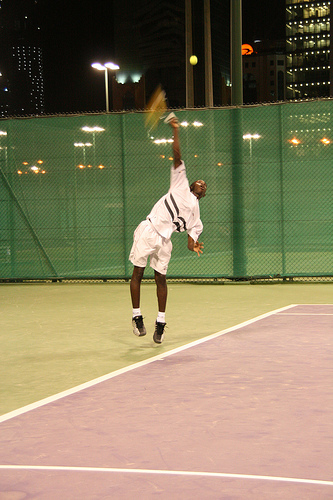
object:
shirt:
[145, 158, 204, 244]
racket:
[139, 88, 175, 137]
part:
[131, 410, 194, 435]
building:
[0, 0, 43, 118]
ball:
[188, 54, 197, 66]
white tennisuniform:
[127, 218, 173, 279]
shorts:
[127, 216, 172, 277]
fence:
[0, 95, 332, 284]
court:
[0, 99, 332, 498]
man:
[128, 114, 206, 344]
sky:
[0, 1, 332, 119]